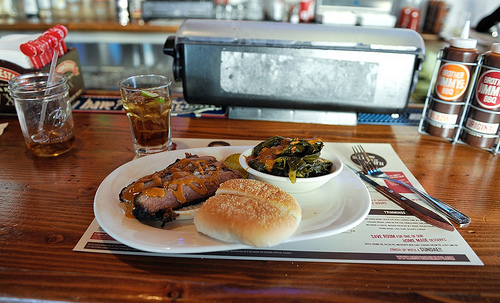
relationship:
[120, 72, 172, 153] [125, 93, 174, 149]
glass has iced tea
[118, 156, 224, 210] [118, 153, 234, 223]
sauce on top of meat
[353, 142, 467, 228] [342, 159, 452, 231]
fork next to knife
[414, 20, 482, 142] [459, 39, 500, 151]
bbq sauce bottle next to bbq sauce bottle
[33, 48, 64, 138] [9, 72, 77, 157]
spoon in jar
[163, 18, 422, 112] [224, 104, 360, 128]
warmer on top of grill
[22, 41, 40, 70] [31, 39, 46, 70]
spoon next to spoon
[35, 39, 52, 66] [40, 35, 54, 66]
spoon next to spoon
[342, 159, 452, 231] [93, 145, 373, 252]
knife next to plate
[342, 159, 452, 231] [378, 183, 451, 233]
knife has handle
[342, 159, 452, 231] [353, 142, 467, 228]
knife next to fork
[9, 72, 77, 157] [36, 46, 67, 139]
jar has straw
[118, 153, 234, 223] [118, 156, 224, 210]
meat has sauce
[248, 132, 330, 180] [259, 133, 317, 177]
vegetable has topping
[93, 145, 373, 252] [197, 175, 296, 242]
plate has bread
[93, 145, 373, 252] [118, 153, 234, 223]
plate has meat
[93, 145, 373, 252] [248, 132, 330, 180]
plate has vegetable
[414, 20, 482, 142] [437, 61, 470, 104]
bbq sauce bottle has label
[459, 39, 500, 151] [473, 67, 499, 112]
bbq sauce bottle has label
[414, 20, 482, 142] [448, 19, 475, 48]
bbq sauce bottle has top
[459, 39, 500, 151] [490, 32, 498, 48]
bbq sauce bottle has top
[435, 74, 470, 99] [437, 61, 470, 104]
mmm bbq word on label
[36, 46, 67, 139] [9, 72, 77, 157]
straw sitting in jar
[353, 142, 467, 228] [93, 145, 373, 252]
fork next to plate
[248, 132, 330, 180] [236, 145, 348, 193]
vegetable in bowl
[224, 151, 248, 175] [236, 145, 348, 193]
pickle hiding beside bowl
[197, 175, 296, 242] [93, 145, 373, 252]
bread on plate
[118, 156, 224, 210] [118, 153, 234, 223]
sauce drizzled on meat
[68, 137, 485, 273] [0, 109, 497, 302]
table mat protects table